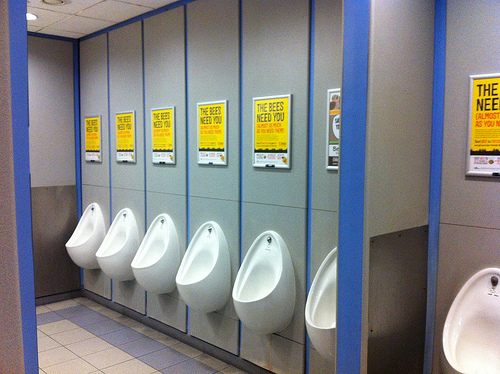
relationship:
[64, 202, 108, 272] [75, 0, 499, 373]
white urinal on wall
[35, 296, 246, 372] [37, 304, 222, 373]
floor tile that blue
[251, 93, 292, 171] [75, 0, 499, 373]
framed advertisement on wall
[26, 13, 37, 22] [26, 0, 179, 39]
white light on ceiling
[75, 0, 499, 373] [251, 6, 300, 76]
wall that gray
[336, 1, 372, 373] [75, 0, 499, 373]
blue trim on wall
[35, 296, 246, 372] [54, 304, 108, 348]
tile floor that blue and grey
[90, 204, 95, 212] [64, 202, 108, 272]
metal bolt on a white urinal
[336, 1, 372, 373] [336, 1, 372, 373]
trim that blue trim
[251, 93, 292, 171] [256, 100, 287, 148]
framed advertisement that yellow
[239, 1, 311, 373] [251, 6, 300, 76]
panel that dark gray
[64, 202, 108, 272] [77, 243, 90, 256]
urinal that white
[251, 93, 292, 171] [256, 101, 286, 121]
framed advertisement that says bees need you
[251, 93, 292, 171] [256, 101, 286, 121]
yellow sign with black writing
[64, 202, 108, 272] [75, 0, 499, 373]
white urinal attached to wall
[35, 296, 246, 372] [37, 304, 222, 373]
row of tiles that are blue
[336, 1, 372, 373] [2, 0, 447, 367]
blue trim in archway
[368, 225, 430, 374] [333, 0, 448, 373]
silver metal on a wall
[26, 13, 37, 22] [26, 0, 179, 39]
white light built into ceiling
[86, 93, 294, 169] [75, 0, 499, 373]
five signs on wall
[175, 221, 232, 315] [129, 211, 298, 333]
white urinal between two urinals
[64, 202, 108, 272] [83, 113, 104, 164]
white urinal under a sign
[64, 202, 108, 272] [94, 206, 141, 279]
white urinal next to a urinal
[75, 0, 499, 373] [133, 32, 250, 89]
wall that gray and blue stripe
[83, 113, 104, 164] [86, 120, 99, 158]
sign that yellow,white & blue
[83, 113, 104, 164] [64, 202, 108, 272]
sign above white urinal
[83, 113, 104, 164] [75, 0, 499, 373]
sign on wall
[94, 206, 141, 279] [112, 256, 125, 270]
urinal that white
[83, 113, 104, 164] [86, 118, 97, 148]
poster that yellow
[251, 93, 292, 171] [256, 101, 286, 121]
poster that sas bees need you